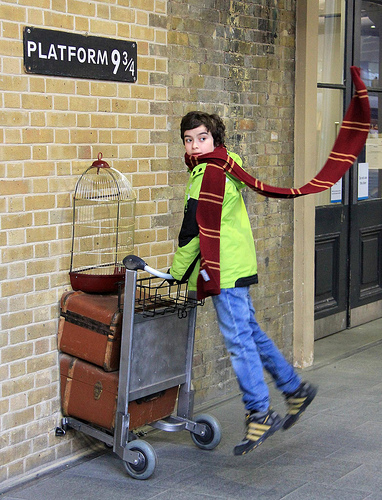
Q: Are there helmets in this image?
A: No, there are no helmets.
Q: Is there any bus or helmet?
A: No, there are no helmets or buses.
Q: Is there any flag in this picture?
A: No, there are no flags.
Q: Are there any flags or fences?
A: No, there are no flags or fences.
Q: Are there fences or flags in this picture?
A: No, there are no flags or fences.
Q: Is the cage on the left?
A: Yes, the cage is on the left of the image.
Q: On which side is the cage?
A: The cage is on the left of the image.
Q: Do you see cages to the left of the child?
A: Yes, there is a cage to the left of the child.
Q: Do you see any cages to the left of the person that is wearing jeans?
A: Yes, there is a cage to the left of the child.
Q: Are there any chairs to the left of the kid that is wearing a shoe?
A: No, there is a cage to the left of the child.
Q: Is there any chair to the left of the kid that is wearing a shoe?
A: No, there is a cage to the left of the child.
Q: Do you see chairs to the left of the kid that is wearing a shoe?
A: No, there is a cage to the left of the child.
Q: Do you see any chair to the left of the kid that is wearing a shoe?
A: No, there is a cage to the left of the child.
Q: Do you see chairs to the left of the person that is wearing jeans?
A: No, there is a cage to the left of the child.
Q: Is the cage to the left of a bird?
A: No, the cage is to the left of the child.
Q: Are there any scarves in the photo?
A: Yes, there is a scarf.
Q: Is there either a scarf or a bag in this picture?
A: Yes, there is a scarf.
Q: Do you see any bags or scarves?
A: Yes, there is a scarf.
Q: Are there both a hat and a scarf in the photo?
A: No, there is a scarf but no hats.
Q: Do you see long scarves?
A: Yes, there is a long scarf.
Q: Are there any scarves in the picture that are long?
A: Yes, there is a scarf that is long.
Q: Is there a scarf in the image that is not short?
A: Yes, there is a long scarf.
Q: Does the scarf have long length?
A: Yes, the scarf is long.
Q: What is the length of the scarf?
A: The scarf is long.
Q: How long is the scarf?
A: The scarf is long.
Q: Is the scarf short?
A: No, the scarf is long.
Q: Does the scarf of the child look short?
A: No, the scarf is long.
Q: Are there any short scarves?
A: No, there is a scarf but it is long.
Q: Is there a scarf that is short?
A: No, there is a scarf but it is long.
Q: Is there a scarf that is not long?
A: No, there is a scarf but it is long.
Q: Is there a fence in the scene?
A: No, there are no fences.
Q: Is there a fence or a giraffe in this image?
A: No, there are no fences or giraffes.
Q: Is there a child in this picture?
A: Yes, there is a child.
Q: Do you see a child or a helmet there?
A: Yes, there is a child.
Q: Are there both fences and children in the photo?
A: No, there is a child but no fences.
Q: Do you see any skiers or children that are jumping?
A: Yes, the child is jumping.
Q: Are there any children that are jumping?
A: Yes, there is a child that is jumping.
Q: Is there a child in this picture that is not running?
A: Yes, there is a child that is jumping.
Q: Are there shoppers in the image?
A: No, there are no shoppers.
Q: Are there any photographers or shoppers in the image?
A: No, there are no shoppers or photographers.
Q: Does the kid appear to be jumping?
A: Yes, the kid is jumping.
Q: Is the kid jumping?
A: Yes, the kid is jumping.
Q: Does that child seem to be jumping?
A: Yes, the child is jumping.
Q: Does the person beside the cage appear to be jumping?
A: Yes, the child is jumping.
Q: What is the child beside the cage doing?
A: The child is jumping.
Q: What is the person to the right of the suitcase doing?
A: The child is jumping.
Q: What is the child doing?
A: The child is jumping.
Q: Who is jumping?
A: The kid is jumping.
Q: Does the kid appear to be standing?
A: No, the kid is jumping.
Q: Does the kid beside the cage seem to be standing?
A: No, the kid is jumping.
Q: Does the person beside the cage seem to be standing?
A: No, the kid is jumping.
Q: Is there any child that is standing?
A: No, there is a child but he is jumping.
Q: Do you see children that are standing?
A: No, there is a child but he is jumping.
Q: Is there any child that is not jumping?
A: No, there is a child but he is jumping.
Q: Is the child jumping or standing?
A: The child is jumping.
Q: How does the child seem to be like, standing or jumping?
A: The child is jumping.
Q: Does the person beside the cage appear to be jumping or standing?
A: The child is jumping.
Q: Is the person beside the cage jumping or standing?
A: The child is jumping.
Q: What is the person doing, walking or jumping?
A: The kid is jumping.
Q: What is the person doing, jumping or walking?
A: The kid is jumping.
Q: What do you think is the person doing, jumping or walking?
A: The kid is jumping.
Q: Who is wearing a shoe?
A: The kid is wearing a shoe.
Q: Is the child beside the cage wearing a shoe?
A: Yes, the child is wearing a shoe.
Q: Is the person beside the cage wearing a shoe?
A: Yes, the child is wearing a shoe.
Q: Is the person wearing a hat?
A: No, the child is wearing a shoe.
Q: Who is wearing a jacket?
A: The child is wearing a jacket.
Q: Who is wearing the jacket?
A: The child is wearing a jacket.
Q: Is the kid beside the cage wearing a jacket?
A: Yes, the kid is wearing a jacket.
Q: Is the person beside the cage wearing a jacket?
A: Yes, the kid is wearing a jacket.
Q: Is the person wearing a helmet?
A: No, the kid is wearing a jacket.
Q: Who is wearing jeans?
A: The child is wearing jeans.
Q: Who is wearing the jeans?
A: The child is wearing jeans.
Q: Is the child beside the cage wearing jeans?
A: Yes, the child is wearing jeans.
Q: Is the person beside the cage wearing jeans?
A: Yes, the child is wearing jeans.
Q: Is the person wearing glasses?
A: No, the child is wearing jeans.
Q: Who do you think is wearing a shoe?
A: The child is wearing a shoe.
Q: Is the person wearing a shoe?
A: Yes, the child is wearing a shoe.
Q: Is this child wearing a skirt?
A: No, the child is wearing a shoe.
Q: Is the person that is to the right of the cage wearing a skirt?
A: No, the child is wearing a shoe.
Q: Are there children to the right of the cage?
A: Yes, there is a child to the right of the cage.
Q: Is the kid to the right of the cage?
A: Yes, the kid is to the right of the cage.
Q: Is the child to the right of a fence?
A: No, the child is to the right of the cage.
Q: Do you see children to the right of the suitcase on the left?
A: Yes, there is a child to the right of the suitcase.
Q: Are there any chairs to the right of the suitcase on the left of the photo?
A: No, there is a child to the right of the suitcase.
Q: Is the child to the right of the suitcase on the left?
A: Yes, the child is to the right of the suitcase.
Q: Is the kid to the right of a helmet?
A: No, the kid is to the right of the suitcase.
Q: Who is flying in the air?
A: The child is flying in the air.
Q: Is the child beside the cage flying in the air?
A: Yes, the kid is flying in the air.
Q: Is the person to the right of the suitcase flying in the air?
A: Yes, the kid is flying in the air.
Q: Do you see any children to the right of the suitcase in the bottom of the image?
A: Yes, there is a child to the right of the suitcase.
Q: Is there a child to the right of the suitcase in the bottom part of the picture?
A: Yes, there is a child to the right of the suitcase.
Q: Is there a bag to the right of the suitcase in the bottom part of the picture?
A: No, there is a child to the right of the suitcase.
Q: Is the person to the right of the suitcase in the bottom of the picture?
A: Yes, the kid is to the right of the suitcase.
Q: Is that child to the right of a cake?
A: No, the child is to the right of the suitcase.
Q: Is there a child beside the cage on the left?
A: Yes, there is a child beside the cage.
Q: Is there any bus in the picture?
A: No, there are no buses.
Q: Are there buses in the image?
A: No, there are no buses.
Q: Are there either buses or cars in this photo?
A: No, there are no buses or cars.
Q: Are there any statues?
A: No, there are no statues.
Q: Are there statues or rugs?
A: No, there are no statues or rugs.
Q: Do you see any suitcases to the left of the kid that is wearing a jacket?
A: Yes, there is a suitcase to the left of the kid.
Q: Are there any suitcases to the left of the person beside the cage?
A: Yes, there is a suitcase to the left of the kid.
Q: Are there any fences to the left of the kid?
A: No, there is a suitcase to the left of the kid.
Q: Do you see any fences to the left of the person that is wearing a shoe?
A: No, there is a suitcase to the left of the kid.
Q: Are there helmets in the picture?
A: No, there are no helmets.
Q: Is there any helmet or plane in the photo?
A: No, there are no helmets or airplanes.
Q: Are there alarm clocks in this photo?
A: No, there are no alarm clocks.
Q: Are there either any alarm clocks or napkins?
A: No, there are no alarm clocks or napkins.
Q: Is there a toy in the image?
A: No, there are no toys.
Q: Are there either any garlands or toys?
A: No, there are no toys or garlands.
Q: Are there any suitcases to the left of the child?
A: Yes, there is a suitcase to the left of the child.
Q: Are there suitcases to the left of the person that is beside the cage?
A: Yes, there is a suitcase to the left of the child.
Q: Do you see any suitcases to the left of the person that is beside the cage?
A: Yes, there is a suitcase to the left of the child.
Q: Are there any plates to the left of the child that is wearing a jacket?
A: No, there is a suitcase to the left of the child.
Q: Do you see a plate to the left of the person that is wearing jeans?
A: No, there is a suitcase to the left of the child.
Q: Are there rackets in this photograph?
A: No, there are no rackets.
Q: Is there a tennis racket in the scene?
A: No, there are no rackets.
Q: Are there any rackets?
A: No, there are no rackets.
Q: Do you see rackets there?
A: No, there are no rackets.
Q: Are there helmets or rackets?
A: No, there are no rackets or helmets.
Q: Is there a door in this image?
A: Yes, there is a door.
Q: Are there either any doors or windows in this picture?
A: Yes, there is a door.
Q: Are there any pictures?
A: No, there are no pictures.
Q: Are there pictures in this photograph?
A: No, there are no pictures.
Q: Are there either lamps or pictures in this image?
A: No, there are no pictures or lamps.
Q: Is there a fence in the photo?
A: No, there are no fences.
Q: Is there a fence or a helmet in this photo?
A: No, there are no fences or helmets.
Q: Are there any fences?
A: No, there are no fences.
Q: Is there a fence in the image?
A: No, there are no fences.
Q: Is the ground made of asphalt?
A: Yes, the ground is made of asphalt.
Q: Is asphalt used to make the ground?
A: Yes, the ground is made of asphalt.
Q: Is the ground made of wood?
A: No, the ground is made of asphalt.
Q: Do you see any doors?
A: Yes, there is a door.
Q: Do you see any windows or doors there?
A: Yes, there is a door.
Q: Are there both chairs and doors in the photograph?
A: No, there is a door but no chairs.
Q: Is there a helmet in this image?
A: No, there are no helmets.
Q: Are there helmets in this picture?
A: No, there are no helmets.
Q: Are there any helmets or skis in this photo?
A: No, there are no helmets or skis.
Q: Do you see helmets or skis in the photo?
A: No, there are no helmets or skis.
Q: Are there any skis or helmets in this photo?
A: No, there are no helmets or skis.